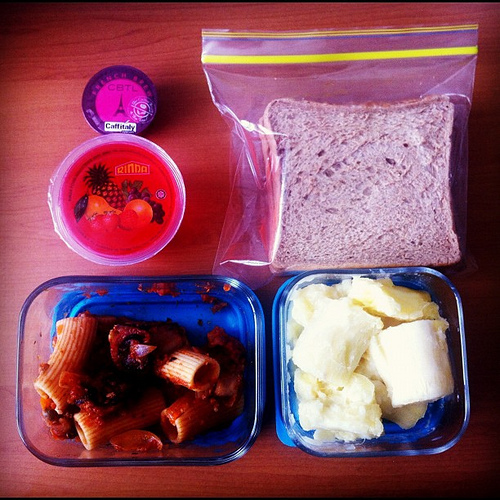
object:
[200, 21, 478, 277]
bag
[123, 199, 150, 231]
fruit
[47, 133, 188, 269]
bowl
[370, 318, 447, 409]
potatoes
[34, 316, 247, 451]
pasta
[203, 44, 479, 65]
seal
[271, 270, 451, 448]
bowl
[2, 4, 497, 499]
table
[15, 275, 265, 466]
bowl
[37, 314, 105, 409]
food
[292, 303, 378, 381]
cheese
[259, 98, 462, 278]
sandwich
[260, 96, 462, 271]
bread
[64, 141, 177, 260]
jello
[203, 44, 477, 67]
stripe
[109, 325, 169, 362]
sauce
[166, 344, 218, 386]
ziti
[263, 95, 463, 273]
slice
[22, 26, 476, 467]
lunch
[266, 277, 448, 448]
lid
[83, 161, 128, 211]
image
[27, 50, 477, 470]
together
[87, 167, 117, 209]
pineapple